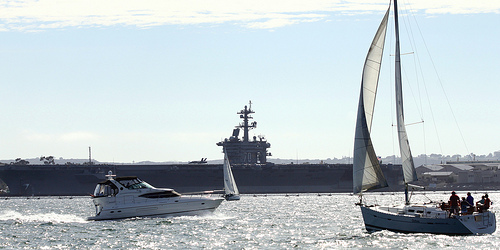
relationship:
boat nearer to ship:
[82, 174, 224, 219] [345, 194, 495, 234]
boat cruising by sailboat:
[87, 170, 225, 221] [335, 36, 495, 240]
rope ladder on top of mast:
[391, 19, 423, 175] [363, 14, 446, 217]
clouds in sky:
[0, 1, 500, 34] [0, 0, 495, 163]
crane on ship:
[79, 142, 99, 165] [1, 95, 351, 188]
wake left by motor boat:
[12, 207, 86, 231] [86, 170, 226, 227]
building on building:
[416, 163, 443, 174] [420, 169, 457, 186]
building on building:
[416, 163, 443, 174] [442, 163, 474, 183]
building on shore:
[416, 163, 443, 174] [406, 181, 498, 191]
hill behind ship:
[6, 157, 160, 179] [90, 170, 225, 220]